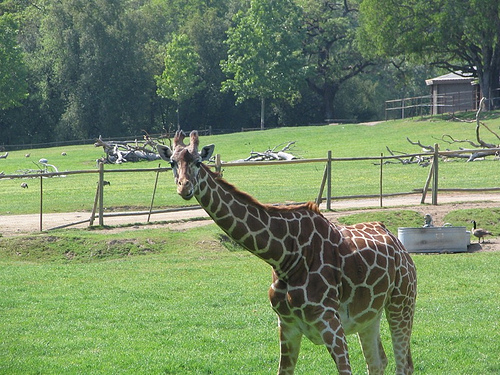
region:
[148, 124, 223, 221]
Head on a giraffe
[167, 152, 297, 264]
Neck on a giraffe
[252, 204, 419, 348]
Body of a giraffe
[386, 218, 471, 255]
Silver water trough in an animal pen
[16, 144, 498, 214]
Wood and metal fence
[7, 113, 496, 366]
dirt path dividing grassy areas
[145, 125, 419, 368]
giraffe with neck leaning forward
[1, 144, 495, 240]
wood and metal fencing along grass edge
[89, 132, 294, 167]
branches and logs in piles on grass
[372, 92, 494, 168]
horizontal trunk with curved branches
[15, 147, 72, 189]
birds walking on grass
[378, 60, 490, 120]
railing in front of small building with gray panel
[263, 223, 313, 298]
wrinkles at base of neck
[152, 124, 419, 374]
A single giraffe.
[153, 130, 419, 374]
A giraffe bending forward.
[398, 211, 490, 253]
A metal trough with some birds by it.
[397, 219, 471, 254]
A metal trough.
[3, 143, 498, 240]
A fence.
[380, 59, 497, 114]
A building surrounded by a fence.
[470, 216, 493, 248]
A goose.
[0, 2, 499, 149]
Wooded area filled with leafy trees.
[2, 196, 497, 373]
Field that the giraffe is in.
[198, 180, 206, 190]
brown spot on giraffe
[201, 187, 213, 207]
brown spot on giraffe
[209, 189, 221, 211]
brown spot on giraffe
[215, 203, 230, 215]
brown spot on giraffe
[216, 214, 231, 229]
brown spot on giraffe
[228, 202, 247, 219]
brown spot on giraffe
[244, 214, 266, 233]
brown spot on giraffe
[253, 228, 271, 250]
brown spot on giraffe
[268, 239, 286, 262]
brown spot on giraffe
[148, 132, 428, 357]
tan and brown giraffe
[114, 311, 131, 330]
short green and yellow grass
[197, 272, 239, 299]
short green and yellow grass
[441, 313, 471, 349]
short green and yellow grass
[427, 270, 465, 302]
short green and yellow grass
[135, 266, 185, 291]
short green and yellow grass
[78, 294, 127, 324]
short green and yellow grass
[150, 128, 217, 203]
The head of the giraffe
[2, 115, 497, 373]
The grass field that the giraffe is standing in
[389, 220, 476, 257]
The water bucket in the field behind the giraffe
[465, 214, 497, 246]
The goose standing next to the water bucket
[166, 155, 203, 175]
eyes of a giraffe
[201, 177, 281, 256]
neck of a giraffe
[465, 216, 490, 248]
bird on the ground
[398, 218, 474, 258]
a round metal pool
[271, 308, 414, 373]
legs of a giraffe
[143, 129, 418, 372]
The giraffe is brown and white.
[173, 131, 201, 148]
The giraffe has two horns on the top of its head.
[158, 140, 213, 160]
The giraffe has two ears on each side of its horns.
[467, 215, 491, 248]
A bird is standing behind the giraffe.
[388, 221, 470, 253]
A metal bucket can be seen behind the giraffe.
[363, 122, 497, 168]
A large pile of wood can be seen behind the giraffe.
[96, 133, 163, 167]
A large pile of wood can be seen from behind the giraffe.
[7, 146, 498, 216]
A gate with wooden posts can be seen behind the giraffe.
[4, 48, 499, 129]
Green trees can be seen from behind the giraffe.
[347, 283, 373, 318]
brown spot on giraffe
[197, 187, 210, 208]
brown spot on giraffe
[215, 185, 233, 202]
brown spot on giraffe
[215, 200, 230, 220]
brown spot on giraffe